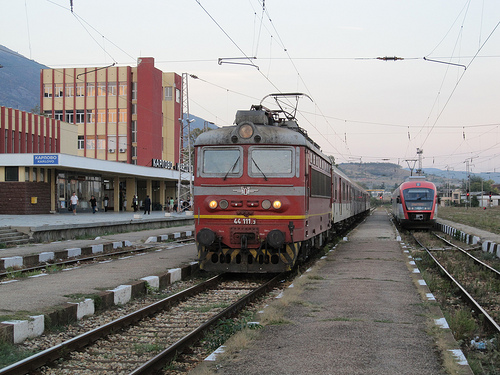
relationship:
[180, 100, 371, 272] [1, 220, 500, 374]
train on railroad track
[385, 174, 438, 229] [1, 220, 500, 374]
train on railroad track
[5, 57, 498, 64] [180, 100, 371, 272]
wire above train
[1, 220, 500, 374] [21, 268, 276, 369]
railroad track on top of rock gravel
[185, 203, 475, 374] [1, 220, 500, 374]
pathway between railroad track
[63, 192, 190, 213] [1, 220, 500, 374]
people are near railroad track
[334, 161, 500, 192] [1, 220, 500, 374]
hills are behind railroad track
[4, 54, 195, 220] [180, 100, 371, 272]
buildings next to train